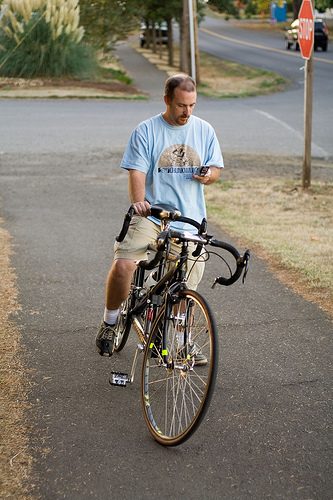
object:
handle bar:
[115, 202, 250, 290]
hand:
[192, 166, 211, 184]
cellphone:
[198, 166, 210, 177]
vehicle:
[285, 20, 329, 51]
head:
[163, 74, 198, 126]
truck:
[168, 13, 175, 66]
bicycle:
[109, 203, 250, 447]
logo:
[158, 143, 201, 172]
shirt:
[120, 113, 225, 235]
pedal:
[109, 371, 130, 387]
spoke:
[145, 375, 177, 385]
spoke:
[172, 371, 176, 436]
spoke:
[183, 375, 209, 377]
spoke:
[182, 341, 210, 365]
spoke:
[187, 299, 192, 354]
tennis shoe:
[178, 342, 207, 364]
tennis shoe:
[94, 319, 116, 358]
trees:
[162, 0, 174, 66]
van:
[140, 25, 169, 47]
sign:
[297, 1, 314, 60]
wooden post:
[303, 60, 312, 190]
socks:
[103, 306, 119, 327]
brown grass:
[205, 154, 332, 315]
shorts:
[112, 211, 205, 300]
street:
[0, 95, 333, 156]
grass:
[133, 46, 278, 102]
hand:
[133, 201, 152, 218]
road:
[193, 16, 333, 154]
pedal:
[169, 313, 189, 326]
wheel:
[141, 289, 219, 448]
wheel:
[105, 257, 132, 353]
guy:
[96, 74, 225, 366]